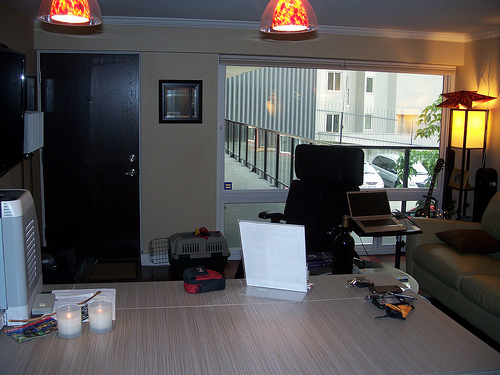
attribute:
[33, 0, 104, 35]
light — small, orange, red, yellow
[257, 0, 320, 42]
light — small, orange, red, yellow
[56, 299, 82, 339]
candle — small, white, illuminated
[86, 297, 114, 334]
candle — small, white, illuminated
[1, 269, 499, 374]
table — wooden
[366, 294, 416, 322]
object — orange, small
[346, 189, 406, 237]
laptop — gray, small, open, silver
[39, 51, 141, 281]
door — black, plain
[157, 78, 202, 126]
mirror — small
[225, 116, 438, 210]
fence — black, small, metal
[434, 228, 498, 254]
pillow — brown, small, dark brown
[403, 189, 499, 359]
couch — light brown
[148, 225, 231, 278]
pet carrier — open, small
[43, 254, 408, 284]
floor — shiny, beige, tile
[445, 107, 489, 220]
lamp — amber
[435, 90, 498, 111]
star — red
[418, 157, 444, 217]
guitar neck — standing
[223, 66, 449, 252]
window — big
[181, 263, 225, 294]
bag — red, black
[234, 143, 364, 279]
chair — black, leather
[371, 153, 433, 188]
mini van — blue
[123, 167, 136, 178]
door handle — silver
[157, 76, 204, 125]
mirror frame — dark